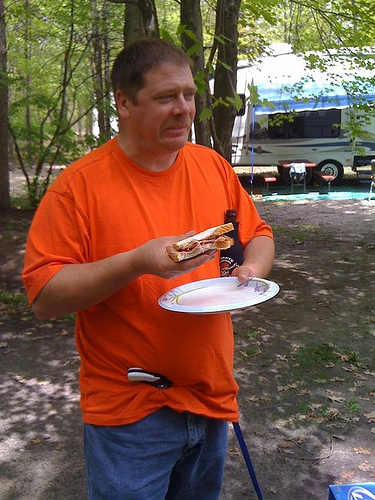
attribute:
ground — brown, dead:
[284, 318, 350, 422]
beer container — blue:
[211, 188, 262, 292]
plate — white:
[154, 239, 289, 347]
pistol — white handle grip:
[116, 351, 182, 403]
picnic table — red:
[249, 140, 332, 217]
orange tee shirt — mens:
[87, 172, 158, 219]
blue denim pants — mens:
[80, 420, 242, 499]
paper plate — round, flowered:
[141, 274, 295, 325]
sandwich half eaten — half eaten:
[166, 220, 250, 277]